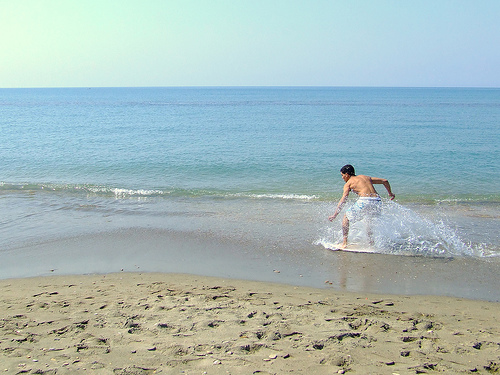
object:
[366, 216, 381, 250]
right leg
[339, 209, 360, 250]
left leg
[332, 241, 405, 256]
surfboard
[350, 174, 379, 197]
strong back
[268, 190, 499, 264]
water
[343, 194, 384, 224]
shorts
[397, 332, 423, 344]
footprints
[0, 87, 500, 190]
ocean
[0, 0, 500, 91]
sky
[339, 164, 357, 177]
hair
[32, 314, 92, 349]
sand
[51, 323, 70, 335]
footprint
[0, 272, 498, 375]
beach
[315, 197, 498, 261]
splash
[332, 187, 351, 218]
extended arms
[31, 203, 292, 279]
sand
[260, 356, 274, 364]
rocks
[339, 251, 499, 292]
sand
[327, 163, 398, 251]
man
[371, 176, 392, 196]
right arm